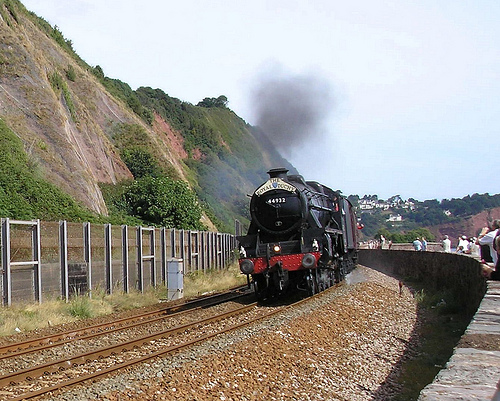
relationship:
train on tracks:
[239, 161, 376, 298] [152, 324, 228, 354]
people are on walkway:
[435, 231, 484, 256] [460, 321, 499, 379]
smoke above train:
[257, 86, 317, 143] [239, 161, 376, 298]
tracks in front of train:
[152, 324, 228, 354] [239, 161, 376, 298]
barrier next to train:
[56, 224, 131, 296] [239, 161, 376, 298]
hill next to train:
[56, 105, 135, 175] [239, 161, 376, 298]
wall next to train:
[4, 218, 40, 308] [239, 161, 376, 298]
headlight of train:
[267, 241, 287, 255] [239, 161, 376, 298]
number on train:
[256, 196, 289, 205] [239, 161, 376, 298]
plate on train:
[250, 254, 312, 268] [239, 161, 376, 298]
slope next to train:
[307, 317, 368, 384] [239, 161, 376, 298]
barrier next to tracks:
[56, 224, 131, 296] [152, 324, 228, 354]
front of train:
[237, 176, 313, 295] [239, 161, 376, 298]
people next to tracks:
[435, 231, 484, 256] [152, 324, 228, 354]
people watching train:
[435, 231, 484, 256] [239, 161, 376, 298]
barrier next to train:
[68, 224, 123, 279] [239, 161, 376, 298]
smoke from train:
[257, 86, 317, 143] [239, 161, 376, 298]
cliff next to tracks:
[175, 133, 205, 191] [152, 324, 228, 354]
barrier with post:
[56, 224, 131, 296] [80, 229, 93, 287]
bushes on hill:
[126, 186, 157, 206] [56, 105, 135, 175]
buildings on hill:
[371, 193, 400, 207] [416, 221, 447, 238]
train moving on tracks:
[239, 161, 376, 298] [152, 324, 228, 354]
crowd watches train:
[436, 229, 474, 251] [239, 161, 376, 298]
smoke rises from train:
[257, 86, 317, 143] [239, 161, 376, 298]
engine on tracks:
[239, 161, 376, 298] [152, 324, 228, 354]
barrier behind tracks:
[56, 224, 131, 296] [152, 324, 228, 354]